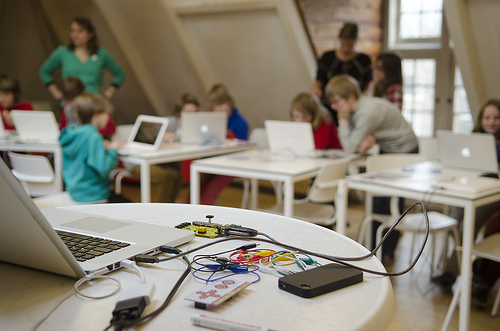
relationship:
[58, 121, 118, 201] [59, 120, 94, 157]
shirt with hood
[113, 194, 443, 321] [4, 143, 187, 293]
wires for computer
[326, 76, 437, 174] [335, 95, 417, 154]
boy wearing sweater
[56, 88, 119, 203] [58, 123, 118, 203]
boy wearing shirt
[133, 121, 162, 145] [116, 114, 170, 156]
monitor face built into computer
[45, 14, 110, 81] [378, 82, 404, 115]
girl wearing shirt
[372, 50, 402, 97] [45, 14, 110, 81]
hair belonging to girl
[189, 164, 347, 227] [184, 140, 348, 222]
legs on table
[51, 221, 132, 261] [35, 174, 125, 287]
buttons on keyboard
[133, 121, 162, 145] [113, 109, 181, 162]
monitor face on laptop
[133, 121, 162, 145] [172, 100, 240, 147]
monitor face on laptop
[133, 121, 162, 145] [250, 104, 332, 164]
monitor face on laptop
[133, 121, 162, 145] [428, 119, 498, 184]
monitor face on laptop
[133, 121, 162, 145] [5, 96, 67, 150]
monitor face on laptop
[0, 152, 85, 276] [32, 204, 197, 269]
cover on laptop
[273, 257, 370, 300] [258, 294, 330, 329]
phone lying on table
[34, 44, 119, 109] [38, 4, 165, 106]
shirt on woman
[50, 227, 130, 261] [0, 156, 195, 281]
keyboard on computer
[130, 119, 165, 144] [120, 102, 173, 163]
monitor face on laptop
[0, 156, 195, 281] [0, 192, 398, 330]
computer on table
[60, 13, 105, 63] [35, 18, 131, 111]
hair on woman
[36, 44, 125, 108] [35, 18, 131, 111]
shirt on woman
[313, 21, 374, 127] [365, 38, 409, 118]
people helping student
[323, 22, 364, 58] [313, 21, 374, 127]
hair on people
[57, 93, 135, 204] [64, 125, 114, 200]
boy wearing shirt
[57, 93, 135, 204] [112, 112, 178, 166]
boy working on computer